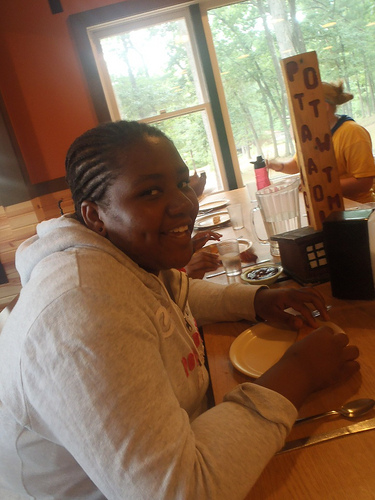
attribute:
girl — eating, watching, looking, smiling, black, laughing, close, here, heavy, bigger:
[49, 116, 228, 375]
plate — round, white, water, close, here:
[231, 321, 302, 376]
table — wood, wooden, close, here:
[291, 449, 373, 499]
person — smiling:
[63, 124, 208, 271]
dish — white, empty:
[227, 321, 353, 387]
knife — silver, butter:
[293, 420, 369, 443]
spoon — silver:
[290, 400, 367, 419]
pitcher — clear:
[253, 177, 308, 241]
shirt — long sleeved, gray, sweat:
[16, 206, 288, 494]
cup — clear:
[218, 244, 243, 277]